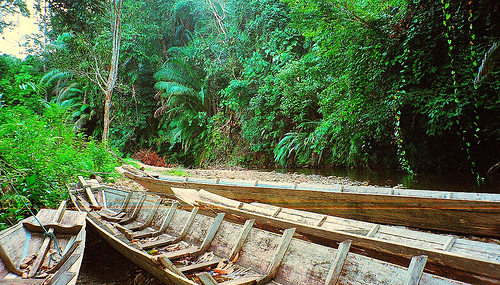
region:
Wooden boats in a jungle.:
[3, 165, 498, 281]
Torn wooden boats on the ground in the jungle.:
[1, 67, 498, 283]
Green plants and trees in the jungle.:
[2, 3, 494, 155]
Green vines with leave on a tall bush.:
[381, 5, 484, 180]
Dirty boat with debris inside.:
[15, 175, 457, 282]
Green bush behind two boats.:
[2, 83, 107, 212]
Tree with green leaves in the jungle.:
[63, 3, 148, 160]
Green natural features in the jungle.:
[4, 2, 499, 153]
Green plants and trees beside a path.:
[154, 0, 499, 168]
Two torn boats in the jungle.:
[120, 157, 499, 273]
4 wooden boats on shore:
[12, 148, 489, 280]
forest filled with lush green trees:
[180, 12, 465, 157]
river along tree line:
[265, 166, 497, 192]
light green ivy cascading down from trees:
[439, 5, 491, 170]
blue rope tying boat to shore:
[7, 159, 104, 273]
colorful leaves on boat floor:
[139, 217, 243, 280]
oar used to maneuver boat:
[24, 195, 81, 271]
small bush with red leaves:
[122, 137, 178, 167]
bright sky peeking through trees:
[5, 4, 70, 65]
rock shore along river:
[188, 154, 394, 194]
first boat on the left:
[6, 198, 93, 281]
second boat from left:
[72, 168, 356, 283]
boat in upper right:
[118, 153, 498, 227]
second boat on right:
[177, 183, 497, 276]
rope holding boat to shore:
[6, 167, 61, 261]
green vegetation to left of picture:
[3, 53, 117, 222]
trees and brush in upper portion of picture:
[55, 3, 498, 186]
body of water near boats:
[220, 154, 498, 194]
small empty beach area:
[141, 154, 377, 186]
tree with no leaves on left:
[86, 5, 129, 158]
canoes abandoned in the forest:
[16, 155, 400, 282]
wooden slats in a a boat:
[144, 199, 214, 249]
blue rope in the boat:
[23, 203, 60, 253]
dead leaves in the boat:
[174, 257, 206, 265]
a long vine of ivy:
[389, 69, 411, 187]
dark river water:
[316, 169, 416, 194]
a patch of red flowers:
[131, 144, 161, 170]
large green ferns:
[146, 60, 203, 147]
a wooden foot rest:
[26, 219, 89, 229]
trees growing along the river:
[214, 19, 328, 136]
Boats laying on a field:
[0, 125, 497, 280]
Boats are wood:
[53, 179, 453, 283]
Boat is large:
[104, 149, 496, 226]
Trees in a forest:
[8, 3, 497, 165]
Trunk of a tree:
[95, 34, 129, 143]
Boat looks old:
[44, 171, 481, 283]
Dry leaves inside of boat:
[134, 224, 249, 284]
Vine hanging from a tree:
[386, 23, 421, 189]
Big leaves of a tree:
[145, 46, 200, 152]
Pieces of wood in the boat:
[102, 196, 295, 278]